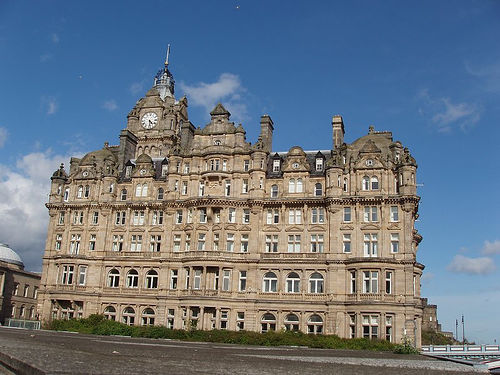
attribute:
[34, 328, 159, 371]
ground — paved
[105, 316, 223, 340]
grass — green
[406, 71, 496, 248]
sky — blue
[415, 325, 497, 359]
bridge — grey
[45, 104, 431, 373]
castle — tan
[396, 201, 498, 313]
sky — cloudy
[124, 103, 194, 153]
clock — black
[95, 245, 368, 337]
windows — arched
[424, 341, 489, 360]
bridge — white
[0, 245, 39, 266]
dome — white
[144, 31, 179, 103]
tower — pointed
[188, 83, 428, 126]
sky — blue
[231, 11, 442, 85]
sky — blue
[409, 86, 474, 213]
sky — blue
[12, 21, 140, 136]
sky — blue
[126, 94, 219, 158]
clock — black, white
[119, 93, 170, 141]
clock — white, black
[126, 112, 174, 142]
clock — black, white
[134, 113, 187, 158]
clock — white, black